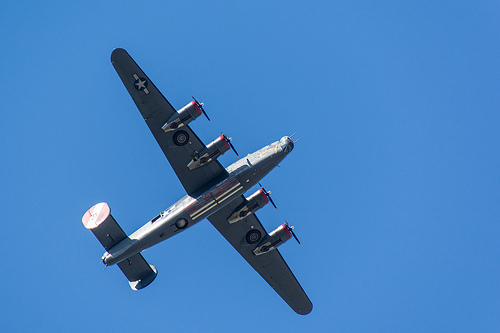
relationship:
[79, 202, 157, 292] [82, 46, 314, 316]
tail of a jet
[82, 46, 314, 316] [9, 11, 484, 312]
jet in sky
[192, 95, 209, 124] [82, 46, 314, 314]
propeller on jet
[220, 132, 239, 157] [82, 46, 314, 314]
propeller on jet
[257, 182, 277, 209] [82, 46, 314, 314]
propeller on jet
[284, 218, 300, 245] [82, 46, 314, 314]
propeller on jet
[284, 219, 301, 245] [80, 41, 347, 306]
propeller on plane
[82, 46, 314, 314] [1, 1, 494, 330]
jet soaring in sky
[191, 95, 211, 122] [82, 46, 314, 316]
propeller on front of jet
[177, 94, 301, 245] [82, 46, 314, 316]
propeller on front of jet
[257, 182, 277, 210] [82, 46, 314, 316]
propeller on front of jet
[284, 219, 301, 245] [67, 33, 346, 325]
propeller on front of plane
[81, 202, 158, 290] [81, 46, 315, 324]
tail of plane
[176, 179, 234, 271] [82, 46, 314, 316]
logo on bottom of jet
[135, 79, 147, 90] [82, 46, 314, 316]
star on bottom of jet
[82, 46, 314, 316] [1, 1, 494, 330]
jet in sky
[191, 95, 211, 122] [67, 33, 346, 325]
propeller on plane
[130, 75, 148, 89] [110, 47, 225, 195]
star on plane wing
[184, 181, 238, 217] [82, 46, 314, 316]
stripe on jet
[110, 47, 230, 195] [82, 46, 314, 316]
plane wing of jet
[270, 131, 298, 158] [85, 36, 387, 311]
front of plane